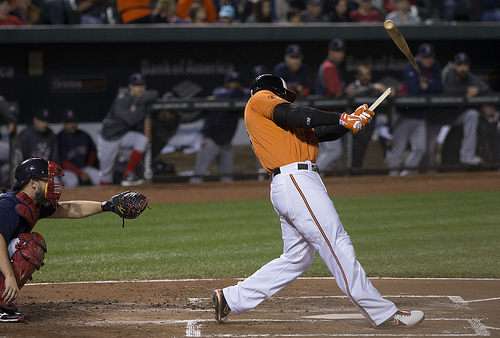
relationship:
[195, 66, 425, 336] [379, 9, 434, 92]
batter swinging bat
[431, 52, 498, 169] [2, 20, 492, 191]
player in dugout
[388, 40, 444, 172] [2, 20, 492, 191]
player in dugout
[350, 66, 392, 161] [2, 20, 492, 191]
player in dugout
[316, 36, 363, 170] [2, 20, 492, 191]
player in dugout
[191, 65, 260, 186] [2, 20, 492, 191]
player in dugout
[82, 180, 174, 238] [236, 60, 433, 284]
catcher behind batter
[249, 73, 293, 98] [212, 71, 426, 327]
hat of batter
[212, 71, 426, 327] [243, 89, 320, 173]
batter orange shirt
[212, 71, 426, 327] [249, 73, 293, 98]
batter wearing a hat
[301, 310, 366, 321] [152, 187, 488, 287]
home plate on field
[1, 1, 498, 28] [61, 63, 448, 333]
people at game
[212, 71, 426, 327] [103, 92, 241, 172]
batter leaning on fence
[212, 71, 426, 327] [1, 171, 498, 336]
batter on field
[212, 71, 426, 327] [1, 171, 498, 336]
batter in field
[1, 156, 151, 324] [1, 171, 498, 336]
catcher in field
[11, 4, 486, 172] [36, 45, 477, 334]
players watching game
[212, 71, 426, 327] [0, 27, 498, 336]
batter playing baseball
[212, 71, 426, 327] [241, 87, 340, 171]
batter wearing shirt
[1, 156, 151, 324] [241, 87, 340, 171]
catcher wearing shirt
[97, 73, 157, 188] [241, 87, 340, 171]
guy wearing shirt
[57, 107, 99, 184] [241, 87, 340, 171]
guy wearing shirt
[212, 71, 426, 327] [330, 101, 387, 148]
batter wearing gloves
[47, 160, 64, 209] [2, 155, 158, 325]
face mask on guy